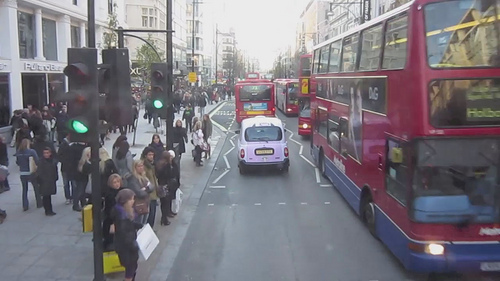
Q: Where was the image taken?
A: It was taken at the city.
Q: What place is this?
A: It is a city.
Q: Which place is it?
A: It is a city.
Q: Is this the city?
A: Yes, it is the city.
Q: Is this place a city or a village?
A: It is a city.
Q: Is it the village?
A: No, it is the city.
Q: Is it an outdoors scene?
A: Yes, it is outdoors.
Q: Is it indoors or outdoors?
A: It is outdoors.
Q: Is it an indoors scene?
A: No, it is outdoors.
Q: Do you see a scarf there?
A: Yes, there is a scarf.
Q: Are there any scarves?
A: Yes, there is a scarf.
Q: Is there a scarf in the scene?
A: Yes, there is a scarf.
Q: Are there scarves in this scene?
A: Yes, there is a scarf.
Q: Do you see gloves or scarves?
A: Yes, there is a scarf.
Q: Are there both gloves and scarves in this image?
A: No, there is a scarf but no gloves.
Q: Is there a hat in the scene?
A: No, there are no hats.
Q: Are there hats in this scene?
A: No, there are no hats.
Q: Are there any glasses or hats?
A: No, there are no hats or glasses.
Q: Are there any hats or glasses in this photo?
A: No, there are no hats or glasses.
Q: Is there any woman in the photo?
A: Yes, there is a woman.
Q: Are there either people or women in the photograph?
A: Yes, there is a woman.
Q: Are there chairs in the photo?
A: No, there are no chairs.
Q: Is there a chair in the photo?
A: No, there are no chairs.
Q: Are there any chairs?
A: No, there are no chairs.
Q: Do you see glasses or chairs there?
A: No, there are no chairs or glasses.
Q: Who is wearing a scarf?
A: The woman is wearing a scarf.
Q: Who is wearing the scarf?
A: The woman is wearing a scarf.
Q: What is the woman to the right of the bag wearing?
A: The woman is wearing a scarf.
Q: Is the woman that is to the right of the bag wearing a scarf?
A: Yes, the woman is wearing a scarf.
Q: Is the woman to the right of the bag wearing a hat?
A: No, the woman is wearing a scarf.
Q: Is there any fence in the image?
A: No, there are no fences.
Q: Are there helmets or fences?
A: No, there are no fences or helmets.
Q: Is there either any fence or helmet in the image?
A: No, there are no fences or helmets.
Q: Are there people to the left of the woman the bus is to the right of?
A: Yes, there is a person to the left of the woman.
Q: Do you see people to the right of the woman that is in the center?
A: No, the person is to the left of the woman.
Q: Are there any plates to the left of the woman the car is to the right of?
A: No, there is a person to the left of the woman.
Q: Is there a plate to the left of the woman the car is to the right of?
A: No, there is a person to the left of the woman.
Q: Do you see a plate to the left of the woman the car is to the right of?
A: No, there is a person to the left of the woman.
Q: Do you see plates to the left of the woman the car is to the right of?
A: No, there is a person to the left of the woman.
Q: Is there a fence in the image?
A: No, there are no fences.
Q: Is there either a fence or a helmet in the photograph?
A: No, there are no fences or helmets.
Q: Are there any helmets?
A: No, there are no helmets.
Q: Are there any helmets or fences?
A: No, there are no helmets or fences.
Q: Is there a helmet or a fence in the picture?
A: No, there are no helmets or fences.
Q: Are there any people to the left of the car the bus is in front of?
A: Yes, there is a person to the left of the car.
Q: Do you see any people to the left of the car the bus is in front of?
A: Yes, there is a person to the left of the car.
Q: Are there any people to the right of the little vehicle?
A: No, the person is to the left of the car.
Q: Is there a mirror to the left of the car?
A: No, there is a person to the left of the car.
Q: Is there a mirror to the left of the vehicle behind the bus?
A: No, there is a person to the left of the car.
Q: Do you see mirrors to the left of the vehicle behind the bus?
A: No, there is a person to the left of the car.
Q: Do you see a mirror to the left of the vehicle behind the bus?
A: No, there is a person to the left of the car.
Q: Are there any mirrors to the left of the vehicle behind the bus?
A: No, there is a person to the left of the car.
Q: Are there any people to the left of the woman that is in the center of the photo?
A: Yes, there is a person to the left of the woman.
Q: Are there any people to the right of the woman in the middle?
A: No, the person is to the left of the woman.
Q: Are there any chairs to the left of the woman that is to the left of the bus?
A: No, there is a person to the left of the woman.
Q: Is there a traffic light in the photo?
A: Yes, there is a traffic light.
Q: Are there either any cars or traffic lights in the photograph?
A: Yes, there is a traffic light.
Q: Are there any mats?
A: No, there are no mats.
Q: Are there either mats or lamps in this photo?
A: No, there are no mats or lamps.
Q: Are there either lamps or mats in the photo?
A: No, there are no mats or lamps.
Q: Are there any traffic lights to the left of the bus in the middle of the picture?
A: Yes, there is a traffic light to the left of the bus.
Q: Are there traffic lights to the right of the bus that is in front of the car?
A: No, the traffic light is to the left of the bus.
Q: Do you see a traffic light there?
A: Yes, there is a traffic light.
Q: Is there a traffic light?
A: Yes, there is a traffic light.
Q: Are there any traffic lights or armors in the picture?
A: Yes, there is a traffic light.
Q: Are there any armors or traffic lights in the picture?
A: Yes, there is a traffic light.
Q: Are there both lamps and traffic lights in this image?
A: No, there is a traffic light but no lamps.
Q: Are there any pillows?
A: No, there are no pillows.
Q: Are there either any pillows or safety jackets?
A: No, there are no pillows or safety jackets.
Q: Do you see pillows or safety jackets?
A: No, there are no pillows or safety jackets.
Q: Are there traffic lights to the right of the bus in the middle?
A: No, the traffic light is to the left of the bus.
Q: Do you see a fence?
A: No, there are no fences.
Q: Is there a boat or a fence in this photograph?
A: No, there are no fences or boats.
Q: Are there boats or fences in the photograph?
A: No, there are no fences or boats.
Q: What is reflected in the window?
A: The buildings are reflected in the window.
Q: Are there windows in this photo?
A: Yes, there is a window.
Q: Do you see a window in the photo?
A: Yes, there is a window.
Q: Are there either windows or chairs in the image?
A: Yes, there is a window.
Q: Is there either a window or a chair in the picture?
A: Yes, there is a window.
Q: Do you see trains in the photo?
A: No, there are no trains.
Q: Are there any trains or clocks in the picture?
A: No, there are no trains or clocks.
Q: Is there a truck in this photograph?
A: No, there are no trucks.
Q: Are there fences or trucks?
A: No, there are no trucks or fences.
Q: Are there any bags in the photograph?
A: Yes, there is a bag.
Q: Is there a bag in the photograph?
A: Yes, there is a bag.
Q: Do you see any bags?
A: Yes, there is a bag.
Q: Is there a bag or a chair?
A: Yes, there is a bag.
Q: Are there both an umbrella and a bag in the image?
A: No, there is a bag but no umbrellas.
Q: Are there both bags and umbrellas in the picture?
A: No, there is a bag but no umbrellas.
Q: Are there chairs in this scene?
A: No, there are no chairs.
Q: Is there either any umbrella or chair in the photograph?
A: No, there are no chairs or umbrellas.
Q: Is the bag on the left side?
A: Yes, the bag is on the left of the image.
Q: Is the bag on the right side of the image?
A: No, the bag is on the left of the image.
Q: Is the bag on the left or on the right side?
A: The bag is on the left of the image.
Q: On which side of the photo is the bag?
A: The bag is on the left of the image.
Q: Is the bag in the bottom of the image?
A: Yes, the bag is in the bottom of the image.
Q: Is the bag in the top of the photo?
A: No, the bag is in the bottom of the image.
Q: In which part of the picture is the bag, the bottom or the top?
A: The bag is in the bottom of the image.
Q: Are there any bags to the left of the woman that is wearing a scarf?
A: Yes, there is a bag to the left of the woman.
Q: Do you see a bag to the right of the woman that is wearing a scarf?
A: No, the bag is to the left of the woman.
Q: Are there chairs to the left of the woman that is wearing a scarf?
A: No, there is a bag to the left of the woman.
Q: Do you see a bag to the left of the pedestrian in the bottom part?
A: Yes, there is a bag to the left of the pedestrian.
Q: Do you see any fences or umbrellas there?
A: No, there are no umbrellas or fences.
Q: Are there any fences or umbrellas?
A: No, there are no umbrellas or fences.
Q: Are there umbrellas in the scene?
A: No, there are no umbrellas.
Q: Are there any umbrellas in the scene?
A: No, there are no umbrellas.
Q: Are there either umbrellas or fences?
A: No, there are no umbrellas or fences.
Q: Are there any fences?
A: No, there are no fences.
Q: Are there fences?
A: No, there are no fences.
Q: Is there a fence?
A: No, there are no fences.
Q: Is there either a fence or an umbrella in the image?
A: No, there are no fences or umbrellas.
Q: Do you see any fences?
A: No, there are no fences.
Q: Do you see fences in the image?
A: No, there are no fences.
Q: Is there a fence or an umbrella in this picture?
A: No, there are no fences or umbrellas.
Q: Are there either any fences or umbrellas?
A: No, there are no fences or umbrellas.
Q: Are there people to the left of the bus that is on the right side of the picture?
A: Yes, there are people to the left of the bus.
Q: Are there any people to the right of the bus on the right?
A: No, the people are to the left of the bus.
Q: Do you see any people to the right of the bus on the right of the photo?
A: No, the people are to the left of the bus.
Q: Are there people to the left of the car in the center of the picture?
A: Yes, there are people to the left of the car.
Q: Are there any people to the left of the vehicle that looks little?
A: Yes, there are people to the left of the car.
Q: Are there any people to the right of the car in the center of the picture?
A: No, the people are to the left of the car.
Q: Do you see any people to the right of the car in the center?
A: No, the people are to the left of the car.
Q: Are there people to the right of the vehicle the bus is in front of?
A: No, the people are to the left of the car.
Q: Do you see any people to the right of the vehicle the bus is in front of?
A: No, the people are to the left of the car.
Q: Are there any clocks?
A: No, there are no clocks.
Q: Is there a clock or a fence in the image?
A: No, there are no clocks or fences.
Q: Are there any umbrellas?
A: No, there are no umbrellas.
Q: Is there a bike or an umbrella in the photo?
A: No, there are no umbrellas or bikes.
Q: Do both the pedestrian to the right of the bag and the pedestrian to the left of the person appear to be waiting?
A: Yes, both the pedestrian and the pedestrian are waiting.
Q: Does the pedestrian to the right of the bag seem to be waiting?
A: Yes, the pedestrian is waiting.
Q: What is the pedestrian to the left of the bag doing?
A: The pedestrian is waiting.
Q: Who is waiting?
A: The pedestrian is waiting.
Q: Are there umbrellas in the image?
A: No, there are no umbrellas.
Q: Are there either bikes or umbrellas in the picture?
A: No, there are no umbrellas or bikes.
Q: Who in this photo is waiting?
A: The pedestrian is waiting.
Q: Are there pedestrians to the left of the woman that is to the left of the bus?
A: Yes, there is a pedestrian to the left of the woman.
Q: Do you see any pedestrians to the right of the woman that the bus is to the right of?
A: No, the pedestrian is to the left of the woman.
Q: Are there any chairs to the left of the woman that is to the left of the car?
A: No, there is a pedestrian to the left of the woman.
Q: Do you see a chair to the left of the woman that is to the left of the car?
A: No, there is a pedestrian to the left of the woman.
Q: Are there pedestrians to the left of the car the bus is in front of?
A: Yes, there is a pedestrian to the left of the car.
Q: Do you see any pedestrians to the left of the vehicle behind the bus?
A: Yes, there is a pedestrian to the left of the car.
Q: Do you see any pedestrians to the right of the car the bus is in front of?
A: No, the pedestrian is to the left of the car.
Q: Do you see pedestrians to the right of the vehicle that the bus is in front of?
A: No, the pedestrian is to the left of the car.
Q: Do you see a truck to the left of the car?
A: No, there is a pedestrian to the left of the car.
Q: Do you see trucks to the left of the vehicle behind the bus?
A: No, there is a pedestrian to the left of the car.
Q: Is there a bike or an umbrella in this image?
A: No, there are no umbrellas or bikes.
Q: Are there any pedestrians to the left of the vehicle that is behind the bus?
A: Yes, there is a pedestrian to the left of the car.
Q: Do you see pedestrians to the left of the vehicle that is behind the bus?
A: Yes, there is a pedestrian to the left of the car.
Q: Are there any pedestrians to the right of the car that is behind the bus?
A: No, the pedestrian is to the left of the car.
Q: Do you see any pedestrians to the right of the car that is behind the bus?
A: No, the pedestrian is to the left of the car.